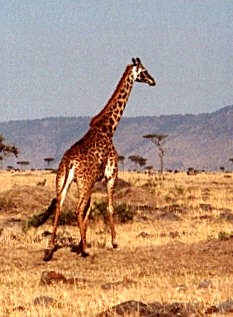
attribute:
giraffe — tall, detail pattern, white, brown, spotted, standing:
[34, 54, 166, 259]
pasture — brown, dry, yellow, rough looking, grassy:
[1, 168, 232, 317]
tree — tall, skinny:
[141, 129, 169, 173]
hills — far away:
[2, 101, 232, 166]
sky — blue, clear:
[0, 1, 230, 115]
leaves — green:
[142, 129, 167, 143]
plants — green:
[29, 200, 139, 228]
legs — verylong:
[51, 182, 116, 258]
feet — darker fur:
[44, 235, 122, 267]